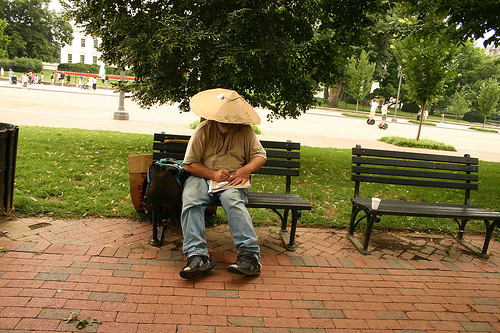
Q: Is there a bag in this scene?
A: Yes, there is a bag.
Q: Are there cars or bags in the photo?
A: Yes, there is a bag.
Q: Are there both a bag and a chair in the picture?
A: No, there is a bag but no chairs.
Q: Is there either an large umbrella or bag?
A: Yes, there is a large bag.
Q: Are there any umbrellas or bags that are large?
A: Yes, the bag is large.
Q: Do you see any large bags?
A: Yes, there is a large bag.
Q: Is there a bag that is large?
A: Yes, there is a bag that is large.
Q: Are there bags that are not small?
A: Yes, there is a large bag.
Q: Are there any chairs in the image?
A: No, there are no chairs.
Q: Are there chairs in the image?
A: No, there are no chairs.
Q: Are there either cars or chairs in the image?
A: No, there are no chairs or cars.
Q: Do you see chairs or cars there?
A: No, there are no chairs or cars.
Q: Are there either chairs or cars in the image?
A: No, there are no chairs or cars.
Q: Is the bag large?
A: Yes, the bag is large.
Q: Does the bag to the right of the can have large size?
A: Yes, the bag is large.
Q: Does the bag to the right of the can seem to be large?
A: Yes, the bag is large.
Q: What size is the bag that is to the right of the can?
A: The bag is large.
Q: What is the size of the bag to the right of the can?
A: The bag is large.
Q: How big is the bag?
A: The bag is large.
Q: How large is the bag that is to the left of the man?
A: The bag is large.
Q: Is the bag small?
A: No, the bag is large.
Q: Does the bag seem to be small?
A: No, the bag is large.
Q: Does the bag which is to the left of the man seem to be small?
A: No, the bag is large.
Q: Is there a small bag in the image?
A: No, there is a bag but it is large.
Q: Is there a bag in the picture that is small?
A: No, there is a bag but it is large.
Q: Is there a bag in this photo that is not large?
A: No, there is a bag but it is large.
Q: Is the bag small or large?
A: The bag is large.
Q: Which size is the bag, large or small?
A: The bag is large.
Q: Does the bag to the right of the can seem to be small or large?
A: The bag is large.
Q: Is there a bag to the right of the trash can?
A: Yes, there is a bag to the right of the trash can.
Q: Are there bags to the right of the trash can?
A: Yes, there is a bag to the right of the trash can.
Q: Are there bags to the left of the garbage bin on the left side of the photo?
A: No, the bag is to the right of the trashcan.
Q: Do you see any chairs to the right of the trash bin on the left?
A: No, there is a bag to the right of the trash bin.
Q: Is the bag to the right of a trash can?
A: Yes, the bag is to the right of a trash can.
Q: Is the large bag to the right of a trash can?
A: Yes, the bag is to the right of a trash can.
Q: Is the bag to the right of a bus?
A: No, the bag is to the right of a trash can.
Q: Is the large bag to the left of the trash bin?
A: No, the bag is to the right of the trash bin.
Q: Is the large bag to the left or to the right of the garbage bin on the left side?
A: The bag is to the right of the trashcan.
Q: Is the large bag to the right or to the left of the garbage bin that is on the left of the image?
A: The bag is to the right of the trashcan.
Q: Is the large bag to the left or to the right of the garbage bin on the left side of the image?
A: The bag is to the right of the trashcan.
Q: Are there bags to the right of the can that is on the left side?
A: Yes, there is a bag to the right of the can.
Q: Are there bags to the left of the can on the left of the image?
A: No, the bag is to the right of the can.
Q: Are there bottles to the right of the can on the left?
A: No, there is a bag to the right of the can.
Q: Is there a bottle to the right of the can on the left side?
A: No, there is a bag to the right of the can.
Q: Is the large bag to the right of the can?
A: Yes, the bag is to the right of the can.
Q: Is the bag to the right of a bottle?
A: No, the bag is to the right of the can.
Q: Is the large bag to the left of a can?
A: No, the bag is to the right of a can.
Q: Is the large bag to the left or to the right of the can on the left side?
A: The bag is to the right of the can.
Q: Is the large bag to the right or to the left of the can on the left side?
A: The bag is to the right of the can.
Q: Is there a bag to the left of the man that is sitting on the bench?
A: Yes, there is a bag to the left of the man.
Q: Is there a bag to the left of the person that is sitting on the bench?
A: Yes, there is a bag to the left of the man.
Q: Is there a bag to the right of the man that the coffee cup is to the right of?
A: No, the bag is to the left of the man.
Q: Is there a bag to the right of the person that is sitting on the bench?
A: No, the bag is to the left of the man.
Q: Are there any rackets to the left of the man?
A: No, there is a bag to the left of the man.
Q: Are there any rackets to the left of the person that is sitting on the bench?
A: No, there is a bag to the left of the man.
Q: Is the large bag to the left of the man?
A: Yes, the bag is to the left of the man.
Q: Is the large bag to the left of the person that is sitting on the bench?
A: Yes, the bag is to the left of the man.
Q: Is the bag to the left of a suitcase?
A: No, the bag is to the left of the man.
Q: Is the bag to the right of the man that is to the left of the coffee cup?
A: No, the bag is to the left of the man.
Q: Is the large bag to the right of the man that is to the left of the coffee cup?
A: No, the bag is to the left of the man.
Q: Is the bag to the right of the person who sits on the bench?
A: No, the bag is to the left of the man.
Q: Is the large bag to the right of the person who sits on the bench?
A: No, the bag is to the left of the man.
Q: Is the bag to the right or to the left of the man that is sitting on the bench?
A: The bag is to the left of the man.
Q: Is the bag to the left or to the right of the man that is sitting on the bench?
A: The bag is to the left of the man.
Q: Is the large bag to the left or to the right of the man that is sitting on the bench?
A: The bag is to the left of the man.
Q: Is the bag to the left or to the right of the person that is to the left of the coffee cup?
A: The bag is to the left of the man.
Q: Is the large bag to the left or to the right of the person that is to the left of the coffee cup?
A: The bag is to the left of the man.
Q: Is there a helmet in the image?
A: No, there are no helmets.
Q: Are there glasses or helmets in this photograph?
A: No, there are no helmets or glasses.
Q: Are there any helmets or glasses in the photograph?
A: No, there are no helmets or glasses.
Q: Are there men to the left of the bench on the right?
A: Yes, there is a man to the left of the bench.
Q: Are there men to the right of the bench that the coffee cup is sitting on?
A: No, the man is to the left of the bench.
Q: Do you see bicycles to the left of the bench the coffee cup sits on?
A: No, there is a man to the left of the bench.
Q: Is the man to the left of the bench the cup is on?
A: Yes, the man is to the left of the bench.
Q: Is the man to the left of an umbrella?
A: No, the man is to the left of the bench.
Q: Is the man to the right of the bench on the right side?
A: No, the man is to the left of the bench.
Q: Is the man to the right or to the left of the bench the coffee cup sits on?
A: The man is to the left of the bench.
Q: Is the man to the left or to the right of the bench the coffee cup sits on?
A: The man is to the left of the bench.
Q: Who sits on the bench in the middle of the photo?
A: The man sits on the bench.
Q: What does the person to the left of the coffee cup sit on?
A: The man sits on the bench.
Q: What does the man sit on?
A: The man sits on the bench.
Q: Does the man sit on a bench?
A: Yes, the man sits on a bench.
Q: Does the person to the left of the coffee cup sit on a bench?
A: Yes, the man sits on a bench.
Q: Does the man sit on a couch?
A: No, the man sits on a bench.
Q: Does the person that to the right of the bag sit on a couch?
A: No, the man sits on a bench.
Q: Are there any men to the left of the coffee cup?
A: Yes, there is a man to the left of the coffee cup.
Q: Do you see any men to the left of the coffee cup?
A: Yes, there is a man to the left of the coffee cup.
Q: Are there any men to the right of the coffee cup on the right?
A: No, the man is to the left of the coffee cup.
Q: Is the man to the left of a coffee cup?
A: Yes, the man is to the left of a coffee cup.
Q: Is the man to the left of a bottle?
A: No, the man is to the left of a coffee cup.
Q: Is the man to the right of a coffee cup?
A: No, the man is to the left of a coffee cup.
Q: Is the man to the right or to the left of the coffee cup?
A: The man is to the left of the coffee cup.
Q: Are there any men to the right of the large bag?
A: Yes, there is a man to the right of the bag.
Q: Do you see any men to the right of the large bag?
A: Yes, there is a man to the right of the bag.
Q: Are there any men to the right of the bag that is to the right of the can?
A: Yes, there is a man to the right of the bag.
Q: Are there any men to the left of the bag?
A: No, the man is to the right of the bag.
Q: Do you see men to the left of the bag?
A: No, the man is to the right of the bag.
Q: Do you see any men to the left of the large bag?
A: No, the man is to the right of the bag.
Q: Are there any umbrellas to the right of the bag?
A: No, there is a man to the right of the bag.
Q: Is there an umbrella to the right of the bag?
A: No, there is a man to the right of the bag.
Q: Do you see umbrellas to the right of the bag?
A: No, there is a man to the right of the bag.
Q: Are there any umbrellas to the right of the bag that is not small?
A: No, there is a man to the right of the bag.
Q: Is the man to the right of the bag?
A: Yes, the man is to the right of the bag.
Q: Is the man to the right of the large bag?
A: Yes, the man is to the right of the bag.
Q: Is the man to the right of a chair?
A: No, the man is to the right of the bag.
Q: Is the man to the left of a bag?
A: No, the man is to the right of a bag.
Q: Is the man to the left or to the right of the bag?
A: The man is to the right of the bag.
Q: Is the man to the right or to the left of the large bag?
A: The man is to the right of the bag.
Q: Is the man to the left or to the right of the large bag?
A: The man is to the right of the bag.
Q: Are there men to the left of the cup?
A: Yes, there is a man to the left of the cup.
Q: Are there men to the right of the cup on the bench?
A: No, the man is to the left of the cup.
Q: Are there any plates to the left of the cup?
A: No, there is a man to the left of the cup.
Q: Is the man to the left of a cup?
A: Yes, the man is to the left of a cup.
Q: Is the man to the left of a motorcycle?
A: No, the man is to the left of a cup.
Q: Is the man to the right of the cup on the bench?
A: No, the man is to the left of the cup.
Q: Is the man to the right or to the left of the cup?
A: The man is to the left of the cup.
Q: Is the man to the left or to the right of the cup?
A: The man is to the left of the cup.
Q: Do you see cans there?
A: Yes, there is a can.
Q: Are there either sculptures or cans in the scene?
A: Yes, there is a can.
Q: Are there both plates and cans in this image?
A: No, there is a can but no plates.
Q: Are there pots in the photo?
A: No, there are no pots.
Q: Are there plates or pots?
A: No, there are no pots or plates.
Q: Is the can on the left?
A: Yes, the can is on the left of the image.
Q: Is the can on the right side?
A: No, the can is on the left of the image.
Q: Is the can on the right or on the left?
A: The can is on the left of the image.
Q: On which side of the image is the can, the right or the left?
A: The can is on the left of the image.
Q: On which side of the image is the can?
A: The can is on the left of the image.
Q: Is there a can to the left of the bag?
A: Yes, there is a can to the left of the bag.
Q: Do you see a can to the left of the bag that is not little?
A: Yes, there is a can to the left of the bag.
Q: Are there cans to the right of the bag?
A: No, the can is to the left of the bag.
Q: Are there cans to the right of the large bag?
A: No, the can is to the left of the bag.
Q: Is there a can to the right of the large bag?
A: No, the can is to the left of the bag.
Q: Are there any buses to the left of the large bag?
A: No, there is a can to the left of the bag.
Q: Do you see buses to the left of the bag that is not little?
A: No, there is a can to the left of the bag.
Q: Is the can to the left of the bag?
A: Yes, the can is to the left of the bag.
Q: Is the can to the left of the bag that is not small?
A: Yes, the can is to the left of the bag.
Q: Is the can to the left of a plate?
A: No, the can is to the left of the bag.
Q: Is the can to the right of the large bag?
A: No, the can is to the left of the bag.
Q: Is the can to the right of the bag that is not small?
A: No, the can is to the left of the bag.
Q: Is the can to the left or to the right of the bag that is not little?
A: The can is to the left of the bag.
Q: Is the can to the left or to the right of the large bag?
A: The can is to the left of the bag.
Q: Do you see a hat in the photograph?
A: Yes, there is a hat.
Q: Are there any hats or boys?
A: Yes, there is a hat.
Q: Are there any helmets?
A: No, there are no helmets.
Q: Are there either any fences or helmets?
A: No, there are no helmets or fences.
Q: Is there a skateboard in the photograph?
A: No, there are no skateboards.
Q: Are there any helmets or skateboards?
A: No, there are no skateboards or helmets.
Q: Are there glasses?
A: No, there are no glasses.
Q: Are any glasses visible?
A: No, there are no glasses.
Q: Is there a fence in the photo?
A: No, there are no fences.